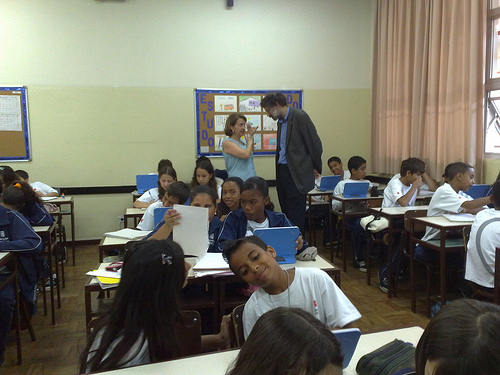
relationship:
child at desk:
[376, 156, 438, 294] [372, 202, 423, 227]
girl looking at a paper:
[143, 182, 223, 259] [170, 200, 210, 257]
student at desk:
[111, 249, 223, 323] [82, 250, 344, 343]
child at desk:
[376, 156, 438, 294] [368, 201, 426, 285]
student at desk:
[138, 182, 190, 238] [111, 223, 228, 241]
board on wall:
[194, 87, 304, 157] [0, 0, 370, 237]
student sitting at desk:
[414, 162, 492, 318] [406, 214, 496, 320]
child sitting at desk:
[376, 156, 438, 294] [371, 203, 428, 298]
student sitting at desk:
[331, 155, 371, 273] [333, 191, 384, 271]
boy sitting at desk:
[218, 234, 360, 342] [87, 324, 424, 373]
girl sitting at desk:
[214, 175, 304, 255] [85, 253, 343, 343]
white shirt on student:
[426, 183, 472, 242] [408, 160, 496, 317]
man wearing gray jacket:
[258, 91, 324, 240] [270, 106, 323, 196]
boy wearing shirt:
[218, 234, 360, 342] [240, 265, 362, 341]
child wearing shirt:
[130, 165, 177, 207] [135, 186, 164, 209]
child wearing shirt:
[379, 155, 437, 290] [380, 175, 418, 207]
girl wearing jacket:
[214, 175, 304, 255] [221, 210, 240, 235]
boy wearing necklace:
[212, 228, 340, 338] [280, 274, 295, 301]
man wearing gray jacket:
[263, 91, 324, 224] [275, 112, 322, 189]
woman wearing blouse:
[219, 110, 260, 184] [220, 132, 256, 187]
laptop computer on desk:
[250, 224, 299, 264] [86, 247, 341, 328]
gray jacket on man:
[270, 106, 323, 196] [258, 86, 325, 253]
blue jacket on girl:
[218, 211, 309, 253] [223, 177, 295, 249]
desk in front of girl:
[411, 196, 499, 300] [423, 137, 476, 274]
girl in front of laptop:
[216, 175, 304, 253] [251, 225, 300, 266]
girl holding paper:
[179, 189, 223, 265] [176, 204, 218, 251]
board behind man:
[194, 89, 303, 157] [258, 91, 324, 240]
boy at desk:
[218, 234, 360, 342] [202, 327, 420, 362]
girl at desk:
[214, 175, 304, 255] [82, 250, 344, 343]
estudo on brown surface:
[198, 94, 214, 154] [189, 91, 251, 154]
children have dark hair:
[3, 155, 481, 350] [48, 148, 465, 316]